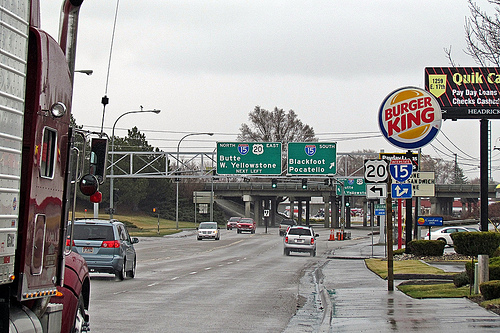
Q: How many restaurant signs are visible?
A: One.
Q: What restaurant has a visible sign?
A: Burger King.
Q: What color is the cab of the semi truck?
A: Red.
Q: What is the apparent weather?
A: Rainy.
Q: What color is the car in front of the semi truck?
A: Gray.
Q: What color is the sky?
A: Gray.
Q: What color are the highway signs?
A: Green white and red.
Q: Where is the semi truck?
A: On the left.